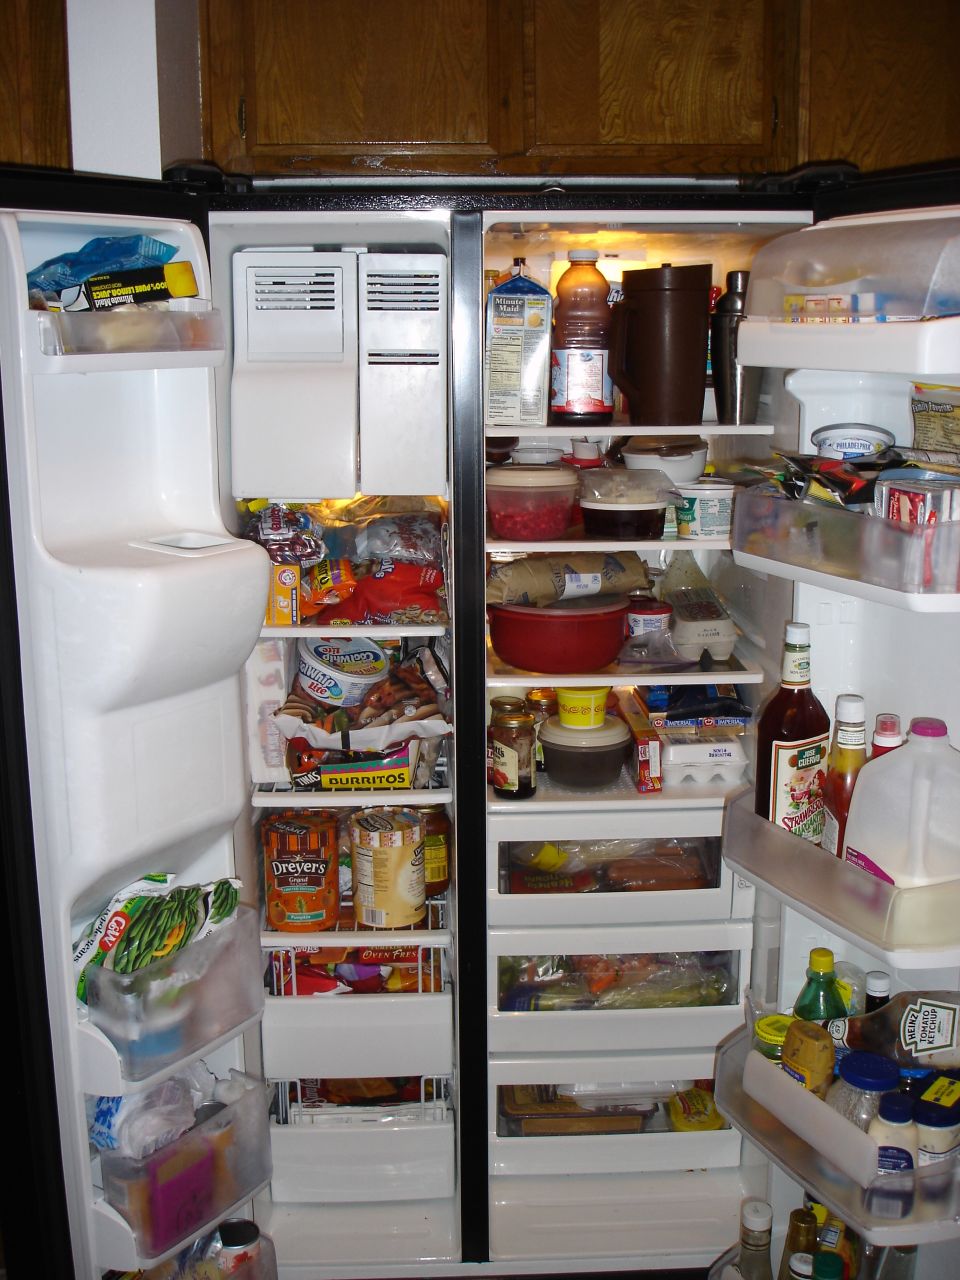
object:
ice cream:
[261, 807, 339, 931]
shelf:
[260, 929, 453, 951]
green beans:
[72, 872, 240, 1022]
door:
[0, 167, 264, 1280]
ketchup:
[755, 947, 960, 1124]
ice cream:
[349, 805, 427, 927]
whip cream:
[297, 638, 390, 709]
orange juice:
[483, 258, 552, 425]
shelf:
[484, 425, 773, 437]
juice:
[552, 248, 616, 425]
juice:
[608, 264, 714, 427]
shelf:
[260, 626, 446, 638]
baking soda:
[266, 565, 301, 626]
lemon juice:
[792, 947, 851, 1047]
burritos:
[285, 717, 453, 788]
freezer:
[0, 173, 461, 1276]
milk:
[842, 715, 960, 945]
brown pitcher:
[608, 264, 714, 427]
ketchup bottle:
[823, 693, 867, 856]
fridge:
[1, 158, 957, 1277]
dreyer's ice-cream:
[261, 807, 339, 929]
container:
[261, 809, 338, 931]